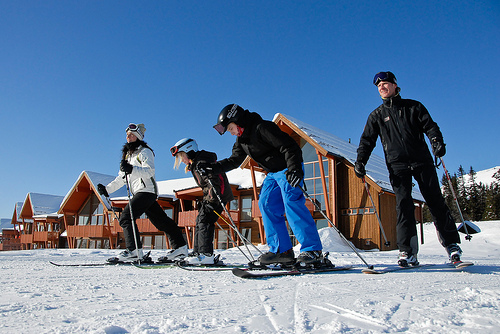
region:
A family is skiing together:
[1, 47, 494, 322]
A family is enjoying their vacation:
[36, 38, 497, 329]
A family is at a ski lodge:
[15, 53, 495, 328]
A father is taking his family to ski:
[30, 57, 496, 327]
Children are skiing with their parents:
[6, 38, 491, 301]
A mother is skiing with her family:
[41, 60, 487, 307]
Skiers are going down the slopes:
[32, 35, 483, 306]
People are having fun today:
[42, 46, 479, 317]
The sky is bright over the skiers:
[18, 50, 493, 321]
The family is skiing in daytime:
[34, 47, 483, 327]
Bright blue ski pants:
[262, 172, 317, 257]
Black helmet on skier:
[213, 101, 250, 131]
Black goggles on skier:
[369, 70, 393, 79]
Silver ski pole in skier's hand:
[126, 168, 139, 258]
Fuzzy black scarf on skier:
[122, 138, 141, 161]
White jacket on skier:
[107, 150, 155, 191]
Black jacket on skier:
[361, 100, 443, 158]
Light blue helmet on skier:
[175, 139, 199, 151]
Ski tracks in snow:
[310, 298, 400, 333]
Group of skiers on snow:
[102, 68, 462, 263]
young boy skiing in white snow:
[211, 109, 309, 253]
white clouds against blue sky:
[5, 11, 87, 82]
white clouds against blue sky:
[7, 72, 71, 134]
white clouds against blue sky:
[20, 109, 62, 157]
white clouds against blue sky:
[97, 22, 161, 59]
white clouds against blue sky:
[122, 48, 202, 118]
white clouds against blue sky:
[217, 9, 294, 53]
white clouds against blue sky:
[222, 38, 289, 78]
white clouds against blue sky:
[321, 25, 355, 99]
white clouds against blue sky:
[434, 8, 474, 93]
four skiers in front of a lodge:
[93, 68, 480, 268]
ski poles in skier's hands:
[283, 161, 392, 267]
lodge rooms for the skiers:
[2, 105, 433, 254]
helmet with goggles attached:
[211, 102, 248, 137]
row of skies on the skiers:
[46, 255, 471, 277]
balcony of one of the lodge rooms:
[61, 223, 113, 238]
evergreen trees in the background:
[441, 160, 498, 232]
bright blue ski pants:
[256, 168, 321, 251]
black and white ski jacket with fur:
[103, 140, 158, 198]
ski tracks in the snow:
[253, 277, 438, 331]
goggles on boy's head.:
[213, 118, 225, 133]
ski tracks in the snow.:
[322, 297, 377, 332]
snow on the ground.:
[32, 284, 62, 308]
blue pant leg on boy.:
[262, 186, 272, 253]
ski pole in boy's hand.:
[317, 206, 363, 252]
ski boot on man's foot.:
[397, 251, 417, 263]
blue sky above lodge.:
[205, 65, 248, 88]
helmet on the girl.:
[172, 137, 196, 157]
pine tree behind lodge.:
[467, 171, 479, 208]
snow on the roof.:
[96, 175, 112, 180]